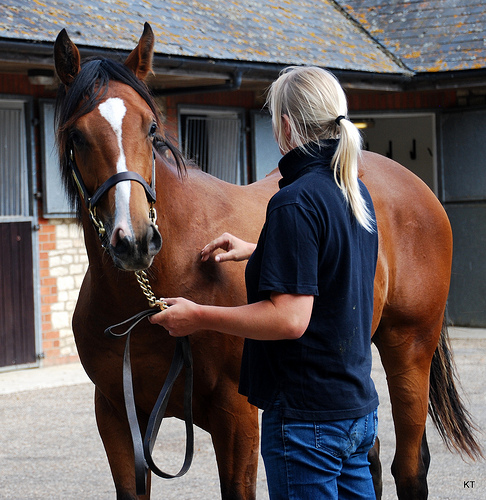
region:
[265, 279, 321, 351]
elbow of a lady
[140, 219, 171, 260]
nostril on a horse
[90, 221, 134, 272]
nostril on a horse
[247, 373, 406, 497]
pair of blue jeans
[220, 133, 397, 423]
dark blue shirt with collar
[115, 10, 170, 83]
large ear on a horse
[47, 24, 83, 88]
large ear on a horse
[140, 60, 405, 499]
lady wearing blue shirt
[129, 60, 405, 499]
lady wearing blue jeans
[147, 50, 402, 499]
lady near a horse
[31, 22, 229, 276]
Brown horse with black mane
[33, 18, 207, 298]
Leather bridle with metal accents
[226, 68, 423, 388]
Woman rider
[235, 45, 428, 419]
Woman in black polo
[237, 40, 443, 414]
Blond woman holding bridle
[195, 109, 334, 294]
No saddle on horse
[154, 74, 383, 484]
Woman petting horse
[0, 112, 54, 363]
wooden stable door in background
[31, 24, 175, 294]
White stripe down snout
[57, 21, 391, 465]
Horse taller than woman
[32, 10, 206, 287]
Horse has a brown and white face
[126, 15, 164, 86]
Horse has a pointed ear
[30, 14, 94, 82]
Horse has a pointed ear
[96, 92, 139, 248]
Horse has a white blaze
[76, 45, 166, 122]
Horse has a black mane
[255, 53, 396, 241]
Woman has light blond hair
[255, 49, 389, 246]
Woman's blonde hair is long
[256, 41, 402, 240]
Woman's hair is in ponytail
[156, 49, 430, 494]
Woman preparing to ride horse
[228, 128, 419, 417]
Woman is wearing dark blue shirt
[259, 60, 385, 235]
The woman is blonde.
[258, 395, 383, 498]
The woman's pants are blue.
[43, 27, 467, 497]
The horse is brown.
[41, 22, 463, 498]
Only one horse visible.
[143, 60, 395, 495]
Woman petting a horse.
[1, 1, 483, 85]
The roof is grey.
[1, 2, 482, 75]
Brown spots on roof.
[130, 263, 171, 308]
the chain is gold.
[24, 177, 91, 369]
The building is brick.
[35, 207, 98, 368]
The bricks are red and brown.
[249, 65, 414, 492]
Woman standing next to a horse.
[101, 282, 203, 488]
Woman is holding a leash.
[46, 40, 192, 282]
Horse is facing the camera.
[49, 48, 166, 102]
The mane is black.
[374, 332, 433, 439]
Veins in the leg.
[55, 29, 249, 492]
The horse is mostly brown.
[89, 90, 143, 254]
White on the forehead and nose.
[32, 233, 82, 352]
Building in the background is made of brick.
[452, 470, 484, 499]
KT in the corner of the photo.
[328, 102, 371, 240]
Woman has a ponytail.